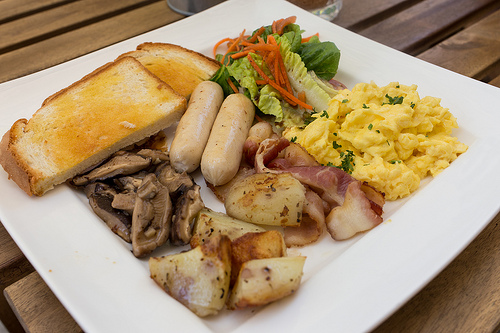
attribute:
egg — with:
[309, 82, 436, 195]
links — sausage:
[168, 85, 235, 185]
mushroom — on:
[112, 172, 173, 258]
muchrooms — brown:
[74, 140, 207, 257]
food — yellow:
[282, 83, 469, 203]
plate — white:
[418, 185, 493, 250]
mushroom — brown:
[67, 148, 159, 190]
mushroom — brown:
[129, 170, 171, 257]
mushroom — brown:
[85, 178, 137, 245]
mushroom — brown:
[155, 163, 195, 193]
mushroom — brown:
[132, 134, 171, 163]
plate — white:
[406, 185, 478, 257]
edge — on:
[60, 254, 171, 333]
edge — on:
[8, 299, 35, 333]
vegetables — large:
[207, 0, 347, 123]